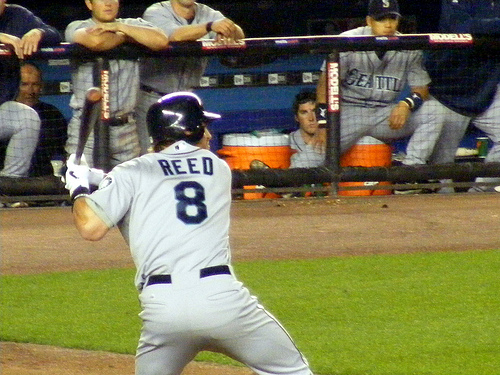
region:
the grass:
[365, 303, 407, 359]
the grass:
[354, 312, 379, 359]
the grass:
[341, 330, 367, 370]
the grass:
[341, 305, 370, 365]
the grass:
[339, 256, 366, 366]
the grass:
[337, 237, 384, 373]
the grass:
[352, 289, 389, 370]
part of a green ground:
[343, 291, 391, 333]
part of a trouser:
[240, 313, 263, 338]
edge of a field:
[66, 339, 93, 354]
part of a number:
[163, 167, 214, 267]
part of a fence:
[338, 105, 388, 187]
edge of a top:
[216, 192, 228, 229]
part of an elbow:
[68, 208, 100, 274]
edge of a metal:
[367, 157, 403, 199]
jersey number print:
[167, 178, 209, 228]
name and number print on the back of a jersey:
[155, 153, 217, 227]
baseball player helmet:
[143, 89, 224, 145]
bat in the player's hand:
[75, 83, 105, 184]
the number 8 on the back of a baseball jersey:
[164, 182, 214, 225]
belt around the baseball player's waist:
[137, 263, 234, 285]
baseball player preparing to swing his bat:
[60, 84, 317, 374]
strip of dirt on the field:
[1, 195, 498, 269]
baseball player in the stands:
[293, 3, 439, 163]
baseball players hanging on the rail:
[1, 0, 252, 200]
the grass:
[319, 321, 366, 361]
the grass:
[331, 331, 352, 367]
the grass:
[315, 295, 345, 370]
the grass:
[401, 267, 420, 371]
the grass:
[356, 321, 367, 363]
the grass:
[326, 342, 341, 371]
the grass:
[317, 332, 341, 372]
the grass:
[328, 338, 338, 365]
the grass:
[358, 340, 383, 370]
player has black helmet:
[127, 84, 220, 148]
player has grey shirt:
[96, 152, 223, 260]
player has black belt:
[133, 250, 258, 296]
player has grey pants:
[126, 281, 305, 361]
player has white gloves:
[53, 145, 110, 202]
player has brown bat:
[71, 81, 95, 175]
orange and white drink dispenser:
[219, 109, 312, 226]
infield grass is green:
[320, 251, 458, 373]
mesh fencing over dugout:
[342, 46, 494, 174]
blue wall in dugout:
[162, 25, 289, 137]